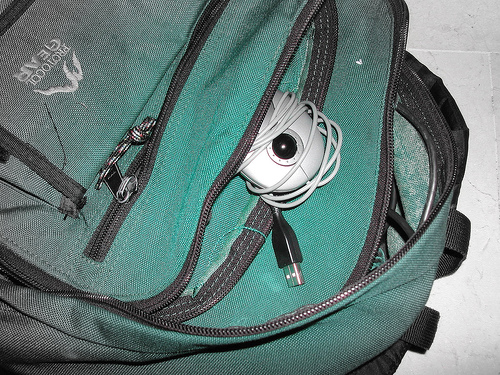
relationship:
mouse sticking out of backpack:
[242, 97, 347, 289] [4, 1, 474, 374]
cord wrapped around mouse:
[243, 88, 338, 283] [242, 97, 347, 289]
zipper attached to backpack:
[79, 6, 228, 255] [4, 1, 474, 374]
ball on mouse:
[273, 130, 295, 160] [242, 97, 347, 289]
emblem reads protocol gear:
[14, 35, 83, 101] [15, 35, 76, 87]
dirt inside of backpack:
[396, 124, 431, 225] [4, 1, 474, 374]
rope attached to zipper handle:
[96, 118, 156, 184] [99, 163, 134, 203]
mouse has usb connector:
[242, 97, 347, 289] [271, 219, 310, 288]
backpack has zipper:
[4, 1, 474, 374] [79, 6, 228, 255]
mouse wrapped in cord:
[242, 97, 347, 289] [243, 88, 338, 283]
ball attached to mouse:
[273, 130, 295, 160] [242, 97, 347, 289]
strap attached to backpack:
[430, 208, 471, 285] [4, 1, 474, 374]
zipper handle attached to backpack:
[99, 163, 134, 203] [4, 1, 474, 374]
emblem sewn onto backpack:
[12, 37, 84, 95] [4, 1, 474, 374]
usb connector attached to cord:
[271, 219, 310, 288] [243, 88, 338, 283]